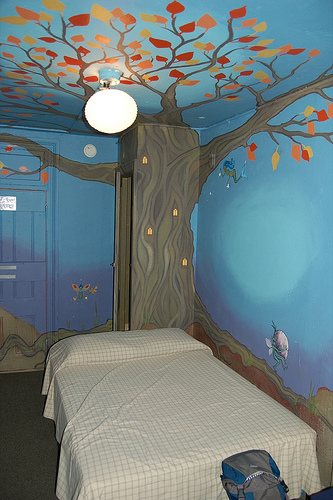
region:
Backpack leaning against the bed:
[221, 448, 288, 496]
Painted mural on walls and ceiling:
[0, 0, 332, 490]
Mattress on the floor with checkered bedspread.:
[41, 326, 323, 498]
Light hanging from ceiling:
[84, 76, 137, 136]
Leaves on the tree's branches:
[0, 6, 331, 182]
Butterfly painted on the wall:
[71, 279, 89, 302]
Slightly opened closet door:
[109, 167, 136, 332]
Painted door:
[0, 135, 59, 374]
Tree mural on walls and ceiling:
[2, 0, 330, 335]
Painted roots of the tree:
[0, 298, 331, 432]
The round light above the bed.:
[86, 81, 142, 136]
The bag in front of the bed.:
[218, 451, 288, 498]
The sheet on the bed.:
[38, 335, 323, 495]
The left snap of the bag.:
[234, 484, 245, 499]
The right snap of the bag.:
[276, 477, 288, 493]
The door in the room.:
[1, 139, 54, 370]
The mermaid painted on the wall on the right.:
[215, 154, 249, 188]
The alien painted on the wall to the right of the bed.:
[261, 317, 293, 369]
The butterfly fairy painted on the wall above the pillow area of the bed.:
[66, 279, 100, 306]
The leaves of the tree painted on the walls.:
[7, 0, 332, 186]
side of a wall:
[311, 347, 314, 352]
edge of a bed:
[202, 461, 208, 474]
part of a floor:
[31, 413, 39, 427]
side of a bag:
[252, 478, 254, 485]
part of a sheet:
[91, 421, 94, 431]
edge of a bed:
[109, 476, 113, 480]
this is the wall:
[227, 204, 329, 324]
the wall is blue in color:
[246, 234, 292, 281]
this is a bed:
[63, 323, 258, 481]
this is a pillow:
[77, 329, 188, 352]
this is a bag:
[218, 453, 282, 498]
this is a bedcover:
[134, 375, 193, 428]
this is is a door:
[9, 160, 51, 328]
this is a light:
[83, 87, 132, 124]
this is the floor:
[10, 381, 40, 433]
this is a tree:
[141, 140, 205, 317]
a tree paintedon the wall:
[62, 43, 308, 336]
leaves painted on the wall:
[197, 96, 294, 193]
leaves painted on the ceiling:
[50, 21, 235, 78]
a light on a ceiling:
[57, 43, 168, 154]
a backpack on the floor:
[221, 438, 276, 486]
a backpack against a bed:
[195, 433, 256, 498]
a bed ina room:
[34, 297, 299, 490]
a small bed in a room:
[65, 329, 234, 482]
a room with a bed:
[32, 307, 306, 471]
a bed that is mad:
[46, 332, 320, 480]